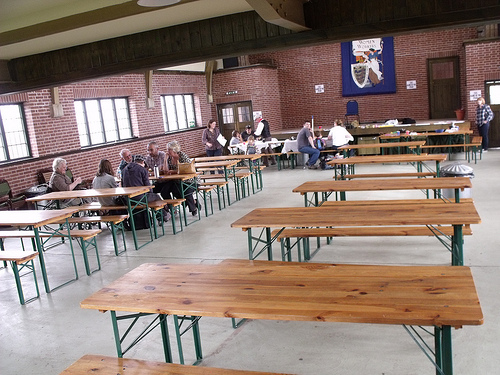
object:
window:
[74, 95, 140, 150]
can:
[440, 162, 475, 179]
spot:
[298, 357, 305, 363]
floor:
[0, 322, 45, 375]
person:
[254, 115, 278, 167]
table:
[229, 201, 480, 266]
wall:
[213, 21, 500, 149]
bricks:
[396, 40, 428, 74]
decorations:
[340, 34, 397, 98]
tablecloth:
[228, 141, 248, 156]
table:
[181, 154, 266, 190]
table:
[225, 198, 478, 266]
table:
[291, 176, 472, 208]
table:
[331, 152, 450, 179]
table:
[0, 209, 79, 293]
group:
[42, 139, 201, 232]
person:
[326, 118, 353, 157]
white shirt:
[328, 125, 355, 146]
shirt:
[475, 96, 495, 127]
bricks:
[287, 57, 300, 82]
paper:
[215, 133, 228, 148]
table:
[82, 262, 486, 375]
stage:
[248, 117, 465, 158]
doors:
[215, 100, 256, 155]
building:
[2, 1, 498, 216]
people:
[296, 120, 321, 170]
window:
[0, 103, 40, 164]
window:
[160, 90, 204, 134]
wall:
[0, 70, 212, 212]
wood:
[49, 352, 285, 375]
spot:
[294, 284, 304, 289]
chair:
[344, 98, 361, 125]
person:
[201, 118, 227, 175]